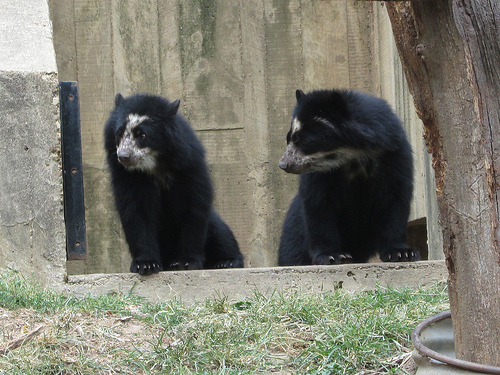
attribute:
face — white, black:
[113, 108, 163, 176]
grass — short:
[12, 291, 406, 368]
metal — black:
[47, 76, 101, 278]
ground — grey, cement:
[20, 273, 496, 363]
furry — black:
[130, 258, 162, 275]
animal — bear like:
[279, 87, 427, 266]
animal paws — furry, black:
[321, 247, 353, 264]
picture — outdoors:
[40, 40, 442, 353]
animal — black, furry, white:
[98, 87, 248, 275]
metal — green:
[400, 297, 493, 374]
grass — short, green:
[126, 289, 388, 318]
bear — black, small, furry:
[271, 88, 423, 263]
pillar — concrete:
[45, 66, 86, 262]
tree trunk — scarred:
[375, 6, 495, 364]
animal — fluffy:
[92, 85, 210, 193]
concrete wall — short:
[67, 260, 444, 299]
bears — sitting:
[93, 82, 433, 264]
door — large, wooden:
[58, 2, 440, 275]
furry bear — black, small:
[96, 86, 231, 262]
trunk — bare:
[379, 0, 499, 375]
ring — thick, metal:
[413, 302, 499, 372]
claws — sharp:
[130, 261, 162, 278]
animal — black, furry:
[270, 81, 426, 269]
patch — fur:
[109, 107, 158, 168]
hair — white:
[114, 108, 159, 176]